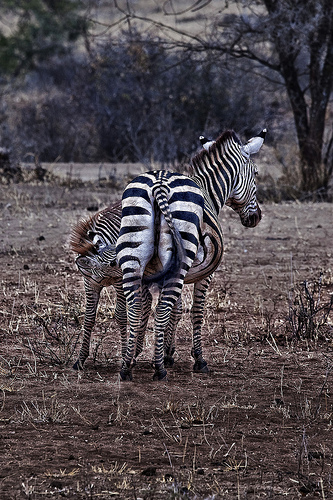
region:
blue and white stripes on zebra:
[178, 188, 207, 230]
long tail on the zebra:
[150, 183, 189, 302]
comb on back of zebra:
[189, 128, 243, 174]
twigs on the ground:
[156, 403, 263, 451]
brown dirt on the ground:
[86, 429, 138, 456]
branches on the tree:
[110, 10, 248, 67]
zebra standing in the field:
[48, 112, 275, 341]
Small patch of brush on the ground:
[59, 464, 109, 485]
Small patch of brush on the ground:
[98, 440, 145, 481]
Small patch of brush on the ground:
[200, 438, 237, 468]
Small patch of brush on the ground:
[253, 453, 290, 483]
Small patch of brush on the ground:
[266, 384, 314, 434]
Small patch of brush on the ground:
[281, 264, 313, 343]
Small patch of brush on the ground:
[214, 310, 252, 350]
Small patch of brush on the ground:
[25, 282, 56, 338]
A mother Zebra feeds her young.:
[110, 128, 268, 380]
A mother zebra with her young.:
[115, 126, 269, 393]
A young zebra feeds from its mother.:
[69, 199, 153, 373]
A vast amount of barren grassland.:
[0, 317, 331, 498]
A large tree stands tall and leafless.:
[90, 0, 331, 198]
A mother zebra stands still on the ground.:
[112, 125, 275, 380]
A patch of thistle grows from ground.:
[268, 264, 332, 352]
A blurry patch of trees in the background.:
[0, 23, 281, 163]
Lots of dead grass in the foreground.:
[2, 304, 332, 499]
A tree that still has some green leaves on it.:
[3, 3, 97, 88]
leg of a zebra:
[151, 286, 174, 380]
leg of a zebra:
[188, 283, 213, 376]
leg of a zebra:
[106, 274, 142, 379]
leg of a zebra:
[71, 282, 84, 365]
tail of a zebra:
[148, 187, 174, 283]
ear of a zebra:
[244, 132, 267, 153]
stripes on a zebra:
[225, 140, 238, 168]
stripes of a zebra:
[180, 180, 200, 227]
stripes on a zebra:
[116, 221, 143, 258]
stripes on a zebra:
[98, 217, 115, 243]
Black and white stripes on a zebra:
[221, 137, 244, 163]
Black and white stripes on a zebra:
[208, 149, 228, 174]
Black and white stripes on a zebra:
[193, 152, 217, 191]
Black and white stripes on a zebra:
[184, 161, 213, 192]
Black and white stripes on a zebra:
[195, 281, 211, 303]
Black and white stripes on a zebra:
[189, 316, 200, 344]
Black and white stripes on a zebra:
[156, 284, 173, 309]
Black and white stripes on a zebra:
[153, 340, 171, 371]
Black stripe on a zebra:
[118, 201, 147, 219]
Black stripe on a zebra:
[111, 221, 146, 240]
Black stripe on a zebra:
[107, 240, 155, 256]